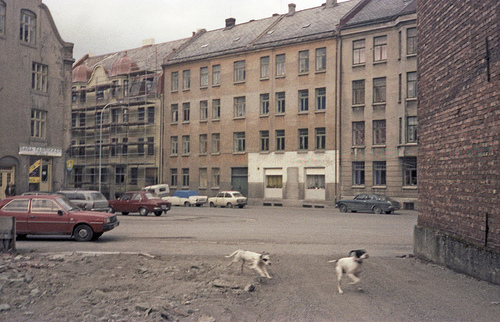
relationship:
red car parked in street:
[103, 189, 172, 221] [170, 212, 404, 240]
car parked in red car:
[0, 193, 120, 241] [103, 189, 172, 221]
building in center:
[158, 10, 349, 214] [151, 0, 344, 307]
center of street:
[151, 0, 344, 307] [20, 190, 485, 320]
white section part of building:
[246, 150, 341, 167] [161, 0, 420, 211]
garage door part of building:
[259, 167, 286, 202] [161, 0, 420, 211]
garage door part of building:
[304, 164, 329, 206] [161, 0, 420, 211]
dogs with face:
[326, 247, 368, 295] [340, 241, 377, 273]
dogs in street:
[326, 247, 368, 295] [199, 188, 408, 290]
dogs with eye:
[326, 247, 368, 295] [258, 257, 267, 272]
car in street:
[0, 193, 120, 241] [45, 223, 330, 299]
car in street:
[57, 183, 110, 215] [129, 202, 416, 312]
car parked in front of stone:
[0, 193, 120, 241] [2, 1, 73, 190]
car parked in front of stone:
[53, 189, 111, 215] [2, 1, 73, 190]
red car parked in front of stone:
[106, 191, 172, 216] [2, 1, 73, 190]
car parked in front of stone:
[18, 187, 68, 205] [2, 1, 73, 190]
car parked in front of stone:
[161, 186, 209, 206] [2, 1, 73, 190]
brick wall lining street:
[412, 0, 495, 286] [20, 190, 485, 320]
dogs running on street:
[330, 247, 370, 292] [20, 190, 485, 320]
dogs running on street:
[224, 247, 273, 278] [20, 190, 485, 320]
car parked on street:
[156, 189, 206, 206] [20, 190, 485, 320]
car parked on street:
[207, 187, 247, 208] [20, 190, 485, 320]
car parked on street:
[0, 193, 120, 241] [20, 190, 485, 320]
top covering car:
[170, 187, 198, 197] [156, 189, 206, 206]